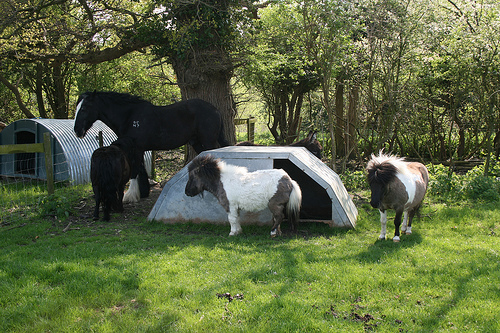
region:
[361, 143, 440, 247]
a mini horse in a field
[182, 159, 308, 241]
a mini horse in a field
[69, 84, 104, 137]
a head of a horse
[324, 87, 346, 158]
a trunk of a tree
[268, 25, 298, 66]
the leaves of a tree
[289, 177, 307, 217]
the tail of a horse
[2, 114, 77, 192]
the front of a shed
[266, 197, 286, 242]
the hind leg of a horse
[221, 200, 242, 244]
the front leg of a horse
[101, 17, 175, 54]
a limb of a tree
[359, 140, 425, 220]
Large black and white animal.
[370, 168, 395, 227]
Animal has black face.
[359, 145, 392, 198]
Animal has black and white mane.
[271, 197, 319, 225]
Animal has gray and white tail.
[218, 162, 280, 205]
Animal has white back.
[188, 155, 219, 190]
Animal has black mane.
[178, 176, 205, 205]
Animal has black face.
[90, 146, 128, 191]
Animal has black tail.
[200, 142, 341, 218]
Little white building behind animal.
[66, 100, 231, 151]
Tall black horse behind little dark animal.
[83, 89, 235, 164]
black horse in yard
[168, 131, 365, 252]
white kennel in front of horse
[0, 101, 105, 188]
grey metal structure behind horse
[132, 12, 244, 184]
large brown tree behind horse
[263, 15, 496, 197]
trees behind animals in yard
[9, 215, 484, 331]
grass is green and short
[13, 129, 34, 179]
door to metal structure is open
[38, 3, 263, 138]
large branches on large tree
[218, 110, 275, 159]
fence behind large tree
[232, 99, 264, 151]
fence behind tree is brown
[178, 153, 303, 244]
brown and white pony in enclosure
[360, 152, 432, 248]
brown and white pony in enclosure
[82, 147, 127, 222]
brown pony in enclosure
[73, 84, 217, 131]
brown and white horse in enclosure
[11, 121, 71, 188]
gray metal shelter in enclosure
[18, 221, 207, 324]
short green grass in enclosure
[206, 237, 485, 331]
short green grass in enclosure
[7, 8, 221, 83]
brown trees with green leaves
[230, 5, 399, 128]
brown trees with green leaves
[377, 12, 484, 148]
brown trees with green leaves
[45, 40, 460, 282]
Horses are standing together.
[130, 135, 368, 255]
The horse is standing next to a little metal structre.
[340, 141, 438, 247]
The little horse is brown and white.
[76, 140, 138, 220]
The backside of the horse.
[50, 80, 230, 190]
A large black horse.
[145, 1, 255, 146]
A thick tree trunk by the big horse.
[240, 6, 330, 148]
A green tree behind the metal tent.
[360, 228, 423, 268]
The shadow of the little brown and white horse.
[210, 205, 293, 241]
The legs of a little horse.